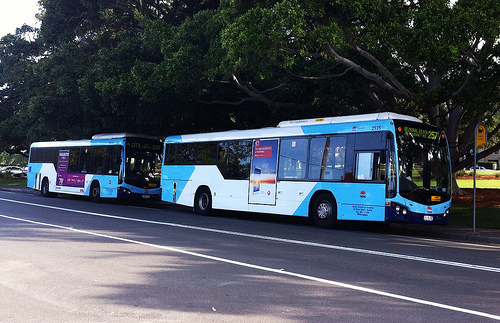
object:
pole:
[472, 121, 488, 232]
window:
[307, 136, 347, 181]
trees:
[215, 0, 499, 196]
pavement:
[0, 190, 500, 323]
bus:
[159, 111, 451, 229]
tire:
[194, 185, 212, 216]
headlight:
[402, 208, 407, 215]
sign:
[476, 124, 486, 147]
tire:
[307, 191, 337, 229]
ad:
[247, 137, 280, 206]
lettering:
[351, 205, 374, 217]